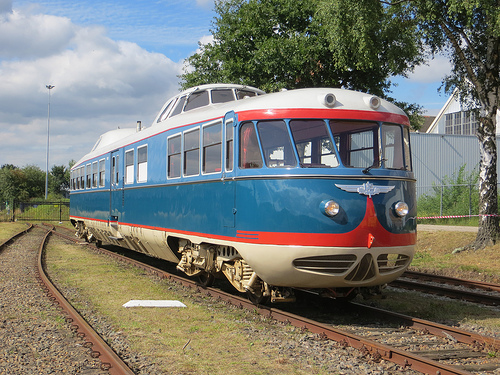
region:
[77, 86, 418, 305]
red, white and blue train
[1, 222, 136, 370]
empty train track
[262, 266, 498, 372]
occupied train track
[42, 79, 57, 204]
tall light post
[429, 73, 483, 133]
white house with windows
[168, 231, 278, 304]
front right wheels of the train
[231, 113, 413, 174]
front engineer windows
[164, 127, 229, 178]
passenger windows on the train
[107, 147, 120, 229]
entrance door on the train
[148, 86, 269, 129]
windows on the roof of the train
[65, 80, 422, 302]
red, white and blue train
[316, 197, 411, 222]
white headlights on the train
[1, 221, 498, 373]
brown train tracks in the grass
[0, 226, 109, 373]
rocks in the train tracks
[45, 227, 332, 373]
grass in between the train tracks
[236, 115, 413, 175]
windshield on the train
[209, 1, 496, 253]
large tree by the train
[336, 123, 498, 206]
blue fence next to the train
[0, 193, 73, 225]
small black fence behind the train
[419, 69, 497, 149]
white house behind the blue fence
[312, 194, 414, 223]
Headlights on front of train.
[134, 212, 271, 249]
Red stripe along section of train.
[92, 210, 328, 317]
Bottom part of train is white.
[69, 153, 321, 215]
Most of train is blue in color.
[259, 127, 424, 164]
Large windshield on front of train car.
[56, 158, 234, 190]
Windows a long side of train car.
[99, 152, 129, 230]
Blue door on side of train.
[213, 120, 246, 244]
Blue door on side of train.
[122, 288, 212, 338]
White object in grass near train.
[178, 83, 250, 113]
Windows on top section of train.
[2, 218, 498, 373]
old red rusty train tracks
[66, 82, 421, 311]
red blue and white train car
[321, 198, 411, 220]
two front headlights of a train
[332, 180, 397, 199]
silver winged emblem on the front of a train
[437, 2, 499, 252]
speckled white and brown tree bark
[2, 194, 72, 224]
black metal fencing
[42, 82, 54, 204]
a tall grey metal light pole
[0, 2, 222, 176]
fluffy grey and white clouds in the sky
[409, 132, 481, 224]
a tall white metal fence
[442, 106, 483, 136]
small grey glass pane windows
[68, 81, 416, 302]
a vintage train parked on the tracks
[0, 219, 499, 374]
a set of rusty railroad tracks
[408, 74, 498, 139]
a white building behind the train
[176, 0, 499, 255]
green trees behind the train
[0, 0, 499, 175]
a partly cloudy sky behind the train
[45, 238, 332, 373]
grass between the railroad tracks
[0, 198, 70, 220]
a black fence behind the train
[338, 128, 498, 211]
a large metal fence in front of the building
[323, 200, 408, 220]
lights on the front of the train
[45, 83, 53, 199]
a tall lamppost behind the train